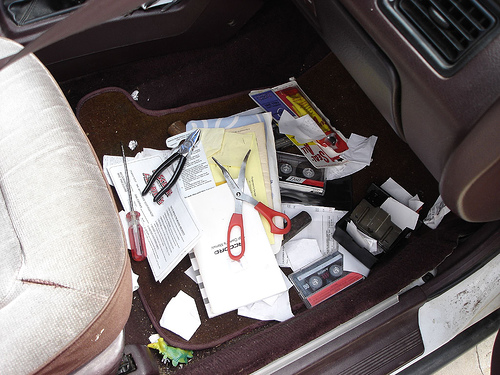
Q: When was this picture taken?
A: During the day.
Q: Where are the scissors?
A: On the floor.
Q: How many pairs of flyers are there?
A: 1.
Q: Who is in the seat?
A: No one.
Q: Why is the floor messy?
A: Something spilled.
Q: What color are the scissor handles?
A: Red.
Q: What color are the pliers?
A: Black.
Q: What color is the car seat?
A: Tan.